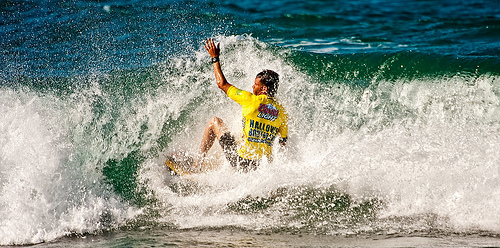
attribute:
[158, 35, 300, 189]
man — wake boarding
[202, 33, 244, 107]
arm — raised up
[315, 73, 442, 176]
watch — color, black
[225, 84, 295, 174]
shirt — yellow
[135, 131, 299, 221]
surfboard — color, orange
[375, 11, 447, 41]
water — blue, color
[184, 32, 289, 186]
person — surfing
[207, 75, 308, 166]
shirt — yellow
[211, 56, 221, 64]
watch — black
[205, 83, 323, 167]
shirt — yellow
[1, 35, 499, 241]
water waves — white, color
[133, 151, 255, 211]
wakeboard — orange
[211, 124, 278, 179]
shorts — black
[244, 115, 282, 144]
words — blue, color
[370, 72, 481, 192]
foam — white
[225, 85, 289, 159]
shirt — yellow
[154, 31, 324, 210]
person — surfing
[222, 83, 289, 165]
t shirt — yellow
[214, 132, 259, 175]
short — black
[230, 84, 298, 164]
shirt — yellow